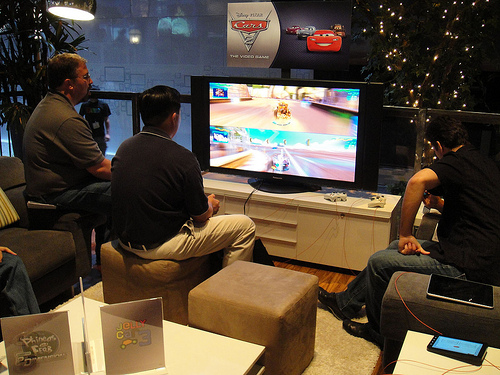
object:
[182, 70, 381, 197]
television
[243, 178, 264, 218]
cord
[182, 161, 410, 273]
stand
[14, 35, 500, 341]
people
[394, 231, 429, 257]
hand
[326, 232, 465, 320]
thigh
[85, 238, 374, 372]
rug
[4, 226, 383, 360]
floor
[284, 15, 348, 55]
car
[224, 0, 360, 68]
advertisement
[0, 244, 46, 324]
jeans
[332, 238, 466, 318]
jeans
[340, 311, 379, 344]
shoes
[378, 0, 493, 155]
lights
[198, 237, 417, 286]
floor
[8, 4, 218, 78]
wall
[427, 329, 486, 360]
computer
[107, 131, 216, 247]
shirt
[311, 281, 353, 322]
shoe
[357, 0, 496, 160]
plant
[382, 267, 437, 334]
cable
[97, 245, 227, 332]
bench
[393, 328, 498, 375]
counter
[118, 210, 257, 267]
khakis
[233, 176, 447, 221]
table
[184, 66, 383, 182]
screen tv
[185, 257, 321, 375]
stool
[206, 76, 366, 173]
game scene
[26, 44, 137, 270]
guy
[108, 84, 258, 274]
guy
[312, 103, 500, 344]
guy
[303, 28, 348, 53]
car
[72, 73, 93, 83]
glass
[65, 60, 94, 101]
man's face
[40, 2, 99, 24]
light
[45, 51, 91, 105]
man's head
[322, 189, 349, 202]
controller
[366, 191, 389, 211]
controller